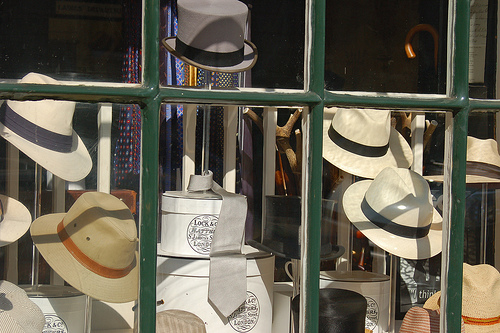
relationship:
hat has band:
[30, 190, 144, 304] [56, 216, 140, 280]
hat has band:
[162, 0, 258, 73] [175, 34, 248, 67]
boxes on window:
[157, 189, 278, 332] [155, 101, 308, 332]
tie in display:
[188, 167, 251, 322] [0, 2, 497, 331]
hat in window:
[30, 190, 144, 304] [155, 101, 308, 332]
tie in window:
[188, 167, 251, 322] [155, 101, 308, 332]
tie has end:
[188, 167, 251, 322] [205, 281, 255, 321]